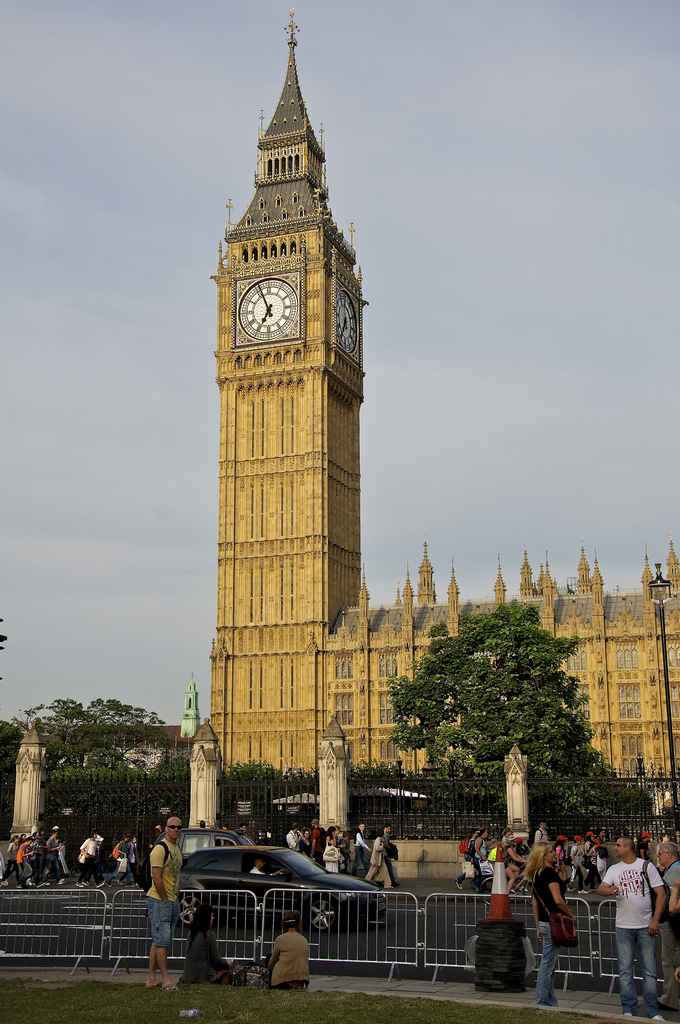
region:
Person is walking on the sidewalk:
[17, 831, 33, 881]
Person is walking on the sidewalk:
[471, 827, 494, 885]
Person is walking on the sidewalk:
[363, 829, 390, 890]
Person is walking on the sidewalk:
[350, 817, 370, 873]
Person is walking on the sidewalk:
[107, 832, 133, 884]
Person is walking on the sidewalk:
[42, 824, 64, 880]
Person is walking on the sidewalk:
[567, 832, 582, 890]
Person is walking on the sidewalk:
[534, 820, 550, 845]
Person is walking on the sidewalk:
[0, 834, 20, 881]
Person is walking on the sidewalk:
[285, 821, 302, 852]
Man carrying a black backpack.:
[128, 812, 188, 993]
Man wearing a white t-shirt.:
[593, 836, 666, 1020]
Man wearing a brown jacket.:
[264, 915, 312, 989]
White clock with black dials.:
[234, 277, 302, 345]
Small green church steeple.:
[178, 671, 201, 740]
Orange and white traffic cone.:
[474, 840, 520, 927]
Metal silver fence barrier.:
[1, 884, 678, 995]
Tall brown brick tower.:
[210, 8, 362, 779]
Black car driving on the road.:
[173, 842, 394, 933]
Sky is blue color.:
[371, 48, 661, 365]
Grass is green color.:
[29, 989, 167, 1022]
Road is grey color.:
[384, 893, 463, 968]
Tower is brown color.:
[229, 148, 349, 618]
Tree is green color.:
[389, 630, 576, 825]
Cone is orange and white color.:
[474, 832, 518, 928]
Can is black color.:
[472, 924, 524, 997]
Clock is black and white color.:
[236, 281, 309, 347]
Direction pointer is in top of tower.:
[280, 10, 309, 52]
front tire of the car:
[307, 897, 338, 924]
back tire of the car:
[175, 891, 206, 925]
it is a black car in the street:
[176, 844, 385, 934]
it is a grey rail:
[0, 875, 649, 993]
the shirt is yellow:
[152, 840, 186, 899]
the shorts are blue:
[147, 894, 176, 953]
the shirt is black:
[533, 872, 565, 918]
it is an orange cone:
[484, 847, 520, 932]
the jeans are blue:
[609, 915, 656, 1008]